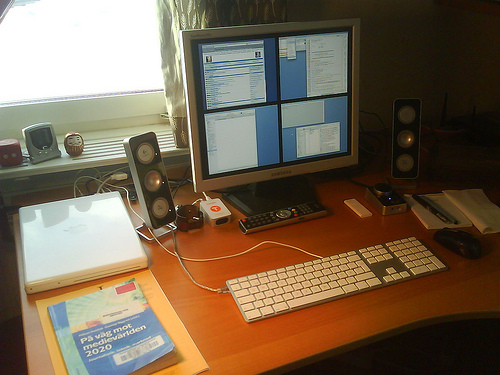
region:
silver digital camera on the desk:
[365, 183, 404, 213]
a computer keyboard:
[217, 239, 447, 324]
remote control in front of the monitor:
[238, 198, 330, 233]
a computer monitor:
[187, 13, 360, 190]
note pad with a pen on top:
[407, 189, 464, 231]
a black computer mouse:
[434, 226, 480, 257]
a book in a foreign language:
[44, 279, 179, 372]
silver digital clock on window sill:
[21, 120, 61, 164]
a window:
[0, 0, 166, 105]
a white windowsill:
[1, 119, 181, 175]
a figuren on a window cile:
[62, 125, 99, 184]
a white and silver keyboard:
[190, 224, 471, 326]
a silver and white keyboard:
[211, 225, 449, 335]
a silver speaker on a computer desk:
[99, 115, 206, 261]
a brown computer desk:
[62, 174, 493, 322]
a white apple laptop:
[11, 183, 152, 312]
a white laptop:
[11, 178, 198, 310]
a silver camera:
[340, 156, 423, 232]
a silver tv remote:
[213, 191, 351, 253]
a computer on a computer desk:
[159, 6, 408, 221]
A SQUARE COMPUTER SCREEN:
[166, 16, 412, 248]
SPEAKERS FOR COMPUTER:
[114, 123, 205, 260]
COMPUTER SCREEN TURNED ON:
[183, 18, 369, 215]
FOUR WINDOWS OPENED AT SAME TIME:
[163, 15, 413, 217]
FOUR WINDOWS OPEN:
[185, 6, 392, 217]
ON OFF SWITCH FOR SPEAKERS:
[364, 170, 424, 235]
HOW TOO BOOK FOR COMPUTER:
[48, 263, 205, 373]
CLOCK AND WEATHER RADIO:
[18, 104, 94, 178]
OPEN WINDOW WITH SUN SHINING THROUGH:
[8, 7, 271, 190]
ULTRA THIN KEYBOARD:
[218, 229, 455, 326]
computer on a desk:
[166, 22, 428, 320]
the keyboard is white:
[220, 224, 443, 334]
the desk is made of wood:
[179, 222, 381, 348]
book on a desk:
[50, 282, 187, 374]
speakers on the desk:
[115, 125, 209, 272]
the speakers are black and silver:
[112, 112, 207, 264]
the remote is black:
[228, 182, 346, 247]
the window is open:
[4, 6, 178, 112]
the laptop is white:
[18, 181, 161, 303]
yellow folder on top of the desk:
[22, 256, 213, 372]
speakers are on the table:
[112, 125, 207, 250]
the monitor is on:
[143, 7, 370, 198]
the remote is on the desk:
[229, 193, 334, 235]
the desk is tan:
[179, 240, 344, 364]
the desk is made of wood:
[166, 233, 278, 354]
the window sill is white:
[14, 110, 179, 160]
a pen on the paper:
[405, 185, 467, 233]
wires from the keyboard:
[125, 232, 311, 274]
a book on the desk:
[27, 267, 194, 369]